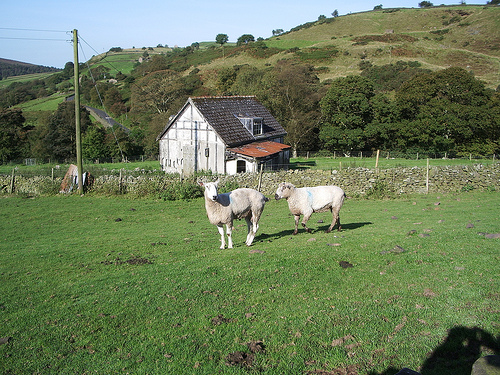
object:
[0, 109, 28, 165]
tree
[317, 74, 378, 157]
tree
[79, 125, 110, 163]
tree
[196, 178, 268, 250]
sheep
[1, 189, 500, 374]
grass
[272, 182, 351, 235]
sheep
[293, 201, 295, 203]
spot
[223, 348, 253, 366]
dirt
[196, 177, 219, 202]
head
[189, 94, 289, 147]
roof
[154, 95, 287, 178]
house